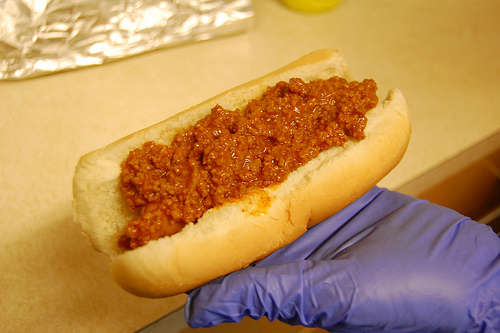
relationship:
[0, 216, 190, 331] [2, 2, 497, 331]
shadow on table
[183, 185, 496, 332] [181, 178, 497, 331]
wrinkles on gloves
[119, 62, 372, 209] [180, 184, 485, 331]
chili dog in hand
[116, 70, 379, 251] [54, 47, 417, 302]
chili on hotdog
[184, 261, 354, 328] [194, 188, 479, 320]
thumb on person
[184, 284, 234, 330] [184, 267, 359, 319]
tip on finger